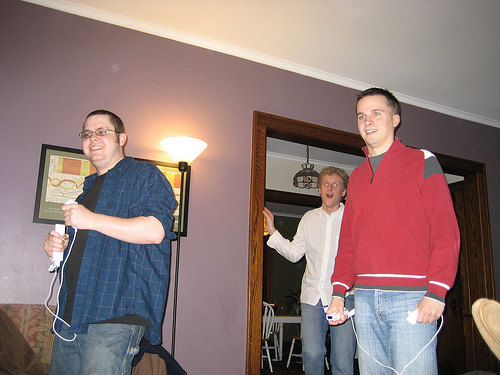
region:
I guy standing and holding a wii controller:
[43, 101, 170, 373]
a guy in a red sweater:
[319, 79, 479, 374]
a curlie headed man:
[261, 151, 369, 373]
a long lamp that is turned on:
[155, 118, 212, 373]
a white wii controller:
[322, 289, 426, 374]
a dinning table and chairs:
[250, 273, 332, 367]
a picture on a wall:
[39, 119, 219, 259]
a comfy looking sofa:
[4, 259, 174, 373]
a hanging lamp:
[283, 132, 330, 197]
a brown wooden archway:
[223, 128, 493, 373]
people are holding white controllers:
[65, 101, 477, 373]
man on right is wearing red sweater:
[335, 136, 478, 316]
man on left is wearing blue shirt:
[40, 160, 162, 315]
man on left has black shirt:
[57, 176, 122, 310]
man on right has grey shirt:
[354, 148, 433, 225]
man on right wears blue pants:
[318, 202, 450, 373]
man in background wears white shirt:
[273, 195, 341, 308]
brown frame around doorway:
[190, 120, 344, 372]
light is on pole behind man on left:
[146, 106, 251, 296]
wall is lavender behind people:
[145, 37, 255, 315]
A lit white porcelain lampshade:
[148, 128, 223, 169]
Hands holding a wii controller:
[45, 197, 85, 278]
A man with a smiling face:
[75, 106, 132, 163]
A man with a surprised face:
[312, 162, 347, 209]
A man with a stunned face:
[346, 85, 408, 147]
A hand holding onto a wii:
[318, 289, 369, 333]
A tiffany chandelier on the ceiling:
[289, 153, 321, 195]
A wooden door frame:
[248, 258, 265, 322]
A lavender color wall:
[207, 204, 241, 321]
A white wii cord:
[40, 292, 77, 345]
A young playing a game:
[326, 89, 463, 371]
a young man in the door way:
[270, 144, 350, 367]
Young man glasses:
[72, 124, 127, 144]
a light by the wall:
[157, 131, 202, 371]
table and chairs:
[263, 295, 301, 362]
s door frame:
[242, 113, 272, 372]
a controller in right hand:
[44, 222, 66, 271]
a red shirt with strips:
[331, 150, 461, 297]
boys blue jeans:
[358, 289, 426, 369]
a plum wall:
[196, 177, 251, 334]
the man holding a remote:
[18, 85, 218, 373]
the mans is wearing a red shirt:
[332, 146, 474, 302]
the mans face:
[308, 168, 345, 204]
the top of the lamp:
[151, 127, 202, 165]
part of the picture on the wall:
[16, 128, 83, 200]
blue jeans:
[358, 322, 445, 372]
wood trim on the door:
[248, 109, 327, 144]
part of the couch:
[2, 299, 39, 366]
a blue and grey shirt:
[86, 252, 155, 329]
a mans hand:
[258, 209, 280, 239]